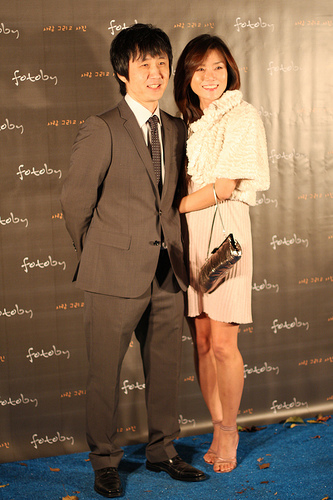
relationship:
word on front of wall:
[10, 69, 61, 87] [1, 0, 333, 463]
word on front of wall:
[16, 162, 63, 180] [1, 0, 333, 463]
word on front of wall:
[232, 17, 276, 33] [1, 0, 333, 463]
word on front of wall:
[43, 24, 88, 34] [1, 0, 333, 463]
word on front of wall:
[78, 69, 117, 80] [1, 0, 333, 463]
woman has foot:
[174, 34, 269, 474] [214, 428, 239, 474]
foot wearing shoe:
[214, 428, 239, 474] [212, 426, 241, 474]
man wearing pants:
[58, 22, 205, 496] [82, 258, 186, 473]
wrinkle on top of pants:
[91, 450, 123, 458] [82, 258, 186, 473]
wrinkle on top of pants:
[147, 430, 180, 450] [82, 258, 186, 473]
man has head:
[58, 22, 205, 496] [109, 25, 172, 101]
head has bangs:
[109, 25, 172, 101] [128, 39, 170, 62]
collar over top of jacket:
[123, 92, 162, 126] [58, 98, 185, 298]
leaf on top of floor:
[256, 461, 272, 471] [0, 413, 332, 499]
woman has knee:
[174, 34, 269, 474] [210, 345, 231, 362]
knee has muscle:
[210, 345, 231, 362] [213, 347, 230, 363]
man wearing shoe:
[58, 22, 205, 496] [93, 466, 123, 500]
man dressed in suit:
[58, 22, 205, 496] [58, 102, 189, 468]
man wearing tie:
[58, 22, 205, 496] [148, 115, 162, 188]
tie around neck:
[148, 115, 162, 188] [123, 91, 159, 117]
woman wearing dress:
[174, 34, 269, 474] [184, 122, 254, 324]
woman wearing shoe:
[174, 34, 269, 474] [212, 426, 241, 474]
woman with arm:
[174, 34, 269, 474] [178, 177, 244, 215]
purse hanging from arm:
[197, 232, 242, 295] [178, 177, 244, 215]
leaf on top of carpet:
[256, 461, 272, 471] [0, 413, 332, 499]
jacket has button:
[58, 98, 185, 298] [156, 208, 164, 218]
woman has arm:
[174, 34, 269, 474] [178, 177, 244, 215]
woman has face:
[174, 34, 269, 474] [190, 57, 228, 99]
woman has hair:
[174, 34, 269, 474] [174, 34, 241, 122]